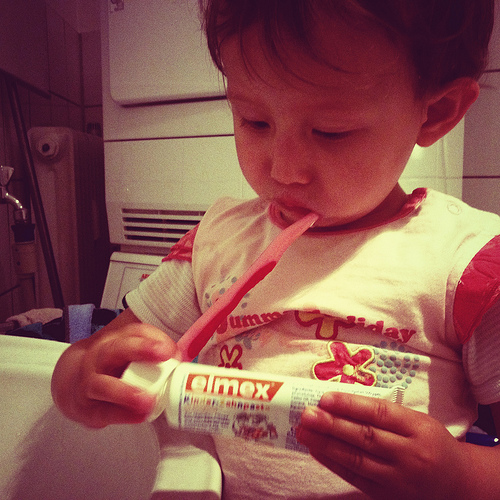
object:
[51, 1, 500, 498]
child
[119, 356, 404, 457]
toothpaste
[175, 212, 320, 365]
toothbrush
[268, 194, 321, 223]
mouth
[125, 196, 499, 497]
shirt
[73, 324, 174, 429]
hand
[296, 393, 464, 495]
hand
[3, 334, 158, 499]
sink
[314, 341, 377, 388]
flower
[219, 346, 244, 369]
flower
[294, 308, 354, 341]
flower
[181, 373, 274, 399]
writing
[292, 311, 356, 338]
border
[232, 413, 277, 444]
drawing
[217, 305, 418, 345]
writing